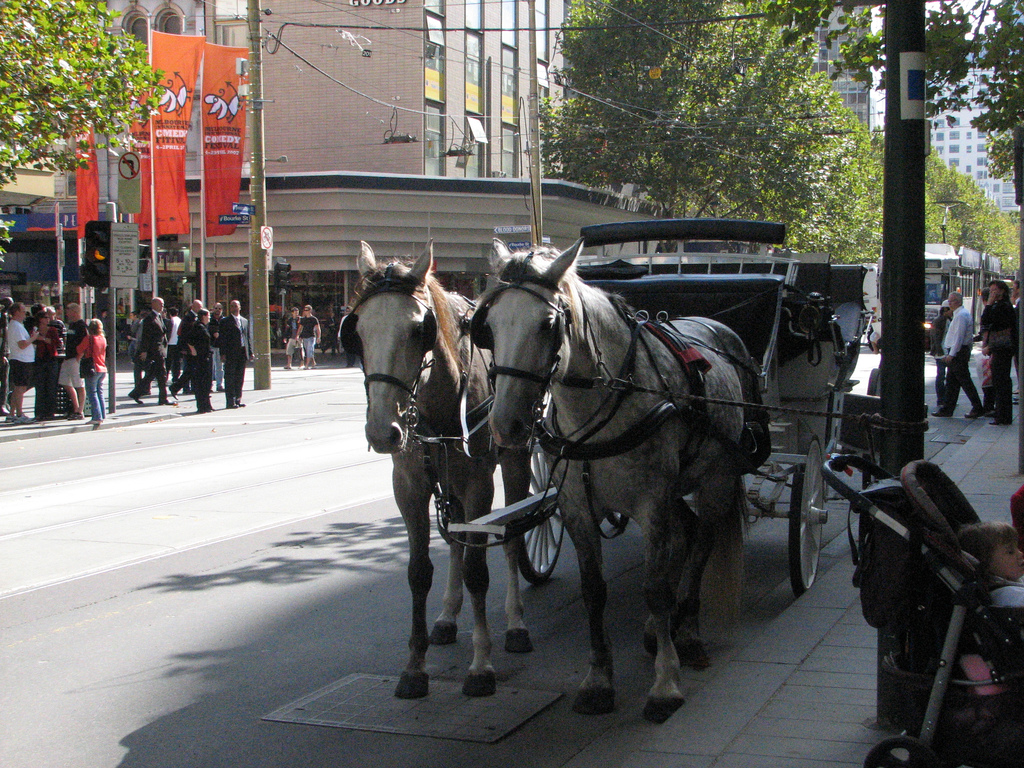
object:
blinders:
[547, 309, 570, 349]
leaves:
[693, 89, 706, 107]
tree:
[679, 128, 886, 266]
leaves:
[78, 42, 98, 59]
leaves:
[966, 206, 998, 239]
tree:
[959, 189, 1007, 257]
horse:
[466, 223, 776, 725]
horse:
[343, 229, 557, 705]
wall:
[0, 0, 704, 353]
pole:
[873, 0, 932, 492]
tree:
[516, 0, 865, 256]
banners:
[197, 41, 252, 240]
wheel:
[783, 430, 833, 598]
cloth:
[534, 297, 778, 483]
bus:
[870, 240, 1021, 358]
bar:
[429, 485, 564, 539]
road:
[0, 320, 1024, 767]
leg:
[391, 476, 436, 702]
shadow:
[130, 505, 521, 597]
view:
[13, 344, 1023, 765]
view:
[0, 0, 1018, 363]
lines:
[21, 529, 189, 557]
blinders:
[419, 305, 441, 355]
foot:
[389, 669, 432, 702]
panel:
[258, 669, 570, 749]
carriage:
[443, 214, 875, 599]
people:
[214, 296, 258, 411]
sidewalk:
[0, 328, 368, 444]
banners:
[148, 26, 210, 241]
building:
[0, 0, 683, 355]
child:
[955, 519, 1024, 645]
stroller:
[815, 447, 1024, 767]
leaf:
[815, 91, 829, 102]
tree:
[756, 0, 1023, 184]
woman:
[75, 316, 110, 427]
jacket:
[75, 334, 109, 375]